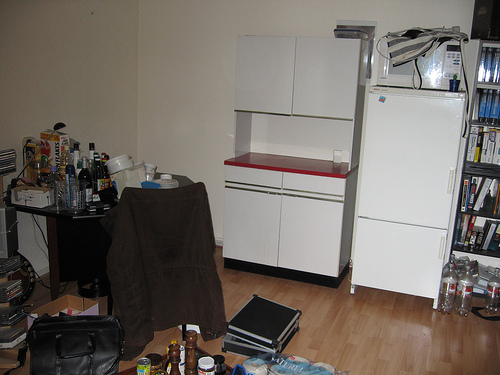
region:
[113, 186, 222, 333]
brown jacket hangs on chair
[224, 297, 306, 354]
small black briefcase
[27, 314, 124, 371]
black luggage bag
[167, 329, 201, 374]
brown salt and pepper shaker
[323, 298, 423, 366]
light brown wooden floors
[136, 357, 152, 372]
a can with yellow label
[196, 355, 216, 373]
a jar of Nutella spread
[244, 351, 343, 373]
pack of toilet tissue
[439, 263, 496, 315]
three empty water bottles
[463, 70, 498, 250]
shelf with books and items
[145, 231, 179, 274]
the coat is brown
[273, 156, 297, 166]
the counter is red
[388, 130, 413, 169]
the fridge is white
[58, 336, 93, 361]
the bag is black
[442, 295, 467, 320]
the bottles are on the floor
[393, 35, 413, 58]
the towel has stripes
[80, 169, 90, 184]
the bottle is black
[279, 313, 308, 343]
the case is on the floor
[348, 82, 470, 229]
white refrigerator in the room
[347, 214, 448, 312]
white freezer in the room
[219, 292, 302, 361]
black and silver case on the floor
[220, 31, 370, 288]
white cabinets with a red counter top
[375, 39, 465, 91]
white microwave on top of the refrigerator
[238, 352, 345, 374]
paper towels on the floor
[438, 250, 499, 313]
empty plastic bottles on the floor by the fridge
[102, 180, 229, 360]
jacket on the back of the chair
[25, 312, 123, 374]
black bag on the floor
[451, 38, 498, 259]
bookshelf next to the fridge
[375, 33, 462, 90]
a white microwave oven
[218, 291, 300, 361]
a black metal case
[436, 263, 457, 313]
an empty water bottle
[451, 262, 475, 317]
an empty water bottle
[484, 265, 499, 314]
an empty water bottle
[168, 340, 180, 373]
a wood salt mill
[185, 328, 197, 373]
a wood pepper mill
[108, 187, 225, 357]
a dark brown jacket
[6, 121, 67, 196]
a small desktop lamp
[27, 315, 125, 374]
a black leather purse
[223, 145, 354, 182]
the counter is red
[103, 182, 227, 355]
jacket on the chair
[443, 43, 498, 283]
shelf beside the fridge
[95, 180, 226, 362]
the jacket is brown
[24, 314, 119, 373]
the bag is black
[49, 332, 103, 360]
handle on bag is black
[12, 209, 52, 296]
cords under the table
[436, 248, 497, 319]
bottles on the floor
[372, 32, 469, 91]
microwave on top of the fridge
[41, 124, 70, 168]
box on the table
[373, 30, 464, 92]
Microwave on top of fridge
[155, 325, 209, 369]
Pepper grinders on table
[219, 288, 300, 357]
Black case on floor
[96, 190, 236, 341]
Brown coat on chair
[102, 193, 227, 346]
Coat hanging on chair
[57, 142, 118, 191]
Bottles on black table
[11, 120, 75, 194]
Skinny lamp on table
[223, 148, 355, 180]
red counter top on white hutch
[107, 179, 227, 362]
brown jacket hanging on back of a chair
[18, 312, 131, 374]
black shiny bag with black handles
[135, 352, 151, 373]
silver aluminum soda can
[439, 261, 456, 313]
clear bottle of liquid with label